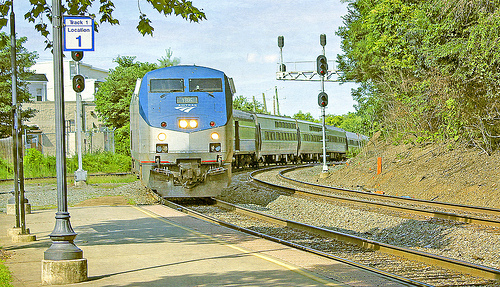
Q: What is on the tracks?
A: Train.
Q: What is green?
A: Trees.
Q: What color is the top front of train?
A: Blue.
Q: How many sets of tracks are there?
A: Two.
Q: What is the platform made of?
A: Concrete.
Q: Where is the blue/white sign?
A: On a pole.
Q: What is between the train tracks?
A: Gravel.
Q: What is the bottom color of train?
A: Silver.